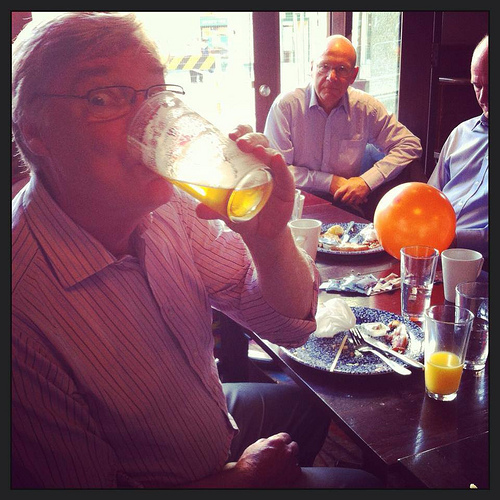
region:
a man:
[22, 186, 202, 430]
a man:
[76, 188, 268, 453]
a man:
[115, 267, 293, 489]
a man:
[158, 285, 235, 480]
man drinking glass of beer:
[28, 22, 305, 270]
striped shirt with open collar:
[42, 217, 182, 428]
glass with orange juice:
[412, 301, 477, 408]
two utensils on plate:
[345, 325, 418, 387]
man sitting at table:
[264, 30, 414, 209]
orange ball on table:
[373, 177, 458, 279]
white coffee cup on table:
[435, 240, 487, 305]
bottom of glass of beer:
[177, 163, 276, 224]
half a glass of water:
[395, 239, 441, 322]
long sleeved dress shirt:
[271, 97, 423, 185]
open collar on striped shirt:
[78, 226, 169, 309]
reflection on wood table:
[403, 411, 465, 463]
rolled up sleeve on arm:
[232, 255, 319, 350]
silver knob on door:
[245, 77, 278, 109]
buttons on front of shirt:
[457, 165, 485, 210]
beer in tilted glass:
[145, 144, 271, 222]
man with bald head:
[307, 31, 361, 107]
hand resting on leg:
[227, 421, 322, 488]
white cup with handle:
[290, 212, 332, 259]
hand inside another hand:
[322, 171, 376, 211]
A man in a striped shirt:
[14, 20, 207, 423]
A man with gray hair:
[16, 15, 191, 256]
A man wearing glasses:
[16, 57, 189, 128]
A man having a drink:
[14, 18, 275, 235]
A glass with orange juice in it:
[417, 295, 479, 416]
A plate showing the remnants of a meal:
[308, 296, 423, 394]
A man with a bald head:
[274, 44, 396, 125]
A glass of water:
[386, 242, 442, 316]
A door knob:
[240, 65, 277, 102]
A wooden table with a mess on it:
[317, 258, 488, 470]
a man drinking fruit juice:
[8, 12, 276, 219]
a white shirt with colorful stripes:
[15, 241, 285, 495]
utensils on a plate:
[346, 322, 421, 379]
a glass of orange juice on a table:
[419, 306, 472, 411]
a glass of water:
[390, 239, 441, 320]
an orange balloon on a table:
[371, 179, 463, 261]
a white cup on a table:
[281, 208, 329, 258]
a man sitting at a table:
[257, 24, 415, 211]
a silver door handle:
[251, 75, 276, 104]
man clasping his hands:
[315, 155, 382, 219]